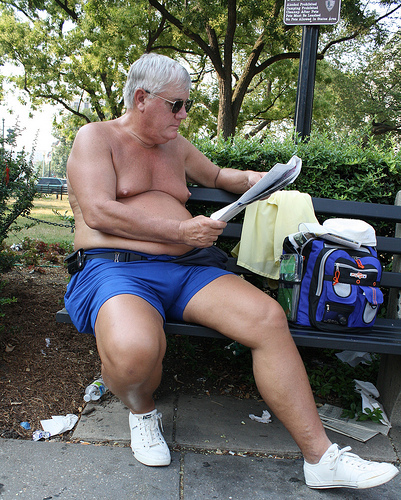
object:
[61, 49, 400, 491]
man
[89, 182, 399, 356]
bench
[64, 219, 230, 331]
sitting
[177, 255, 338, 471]
legs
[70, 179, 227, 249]
arms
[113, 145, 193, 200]
chest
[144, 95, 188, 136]
face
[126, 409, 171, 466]
shoes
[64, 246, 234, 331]
shorts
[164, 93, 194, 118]
sunglasses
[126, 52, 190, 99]
hair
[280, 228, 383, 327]
bag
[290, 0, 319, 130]
poll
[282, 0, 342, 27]
sign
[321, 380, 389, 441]
trash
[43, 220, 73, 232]
chain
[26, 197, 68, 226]
grass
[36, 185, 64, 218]
field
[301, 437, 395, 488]
sneaker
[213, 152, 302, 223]
newspaper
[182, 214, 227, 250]
hand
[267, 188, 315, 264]
shirt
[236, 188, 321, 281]
draped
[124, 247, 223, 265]
fanny pack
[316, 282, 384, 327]
pockets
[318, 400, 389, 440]
newspaper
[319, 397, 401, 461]
ground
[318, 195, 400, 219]
wood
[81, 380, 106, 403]
water bottle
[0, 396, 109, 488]
ground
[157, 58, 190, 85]
forward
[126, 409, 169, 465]
sneakers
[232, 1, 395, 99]
park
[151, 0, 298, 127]
tree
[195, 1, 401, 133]
background